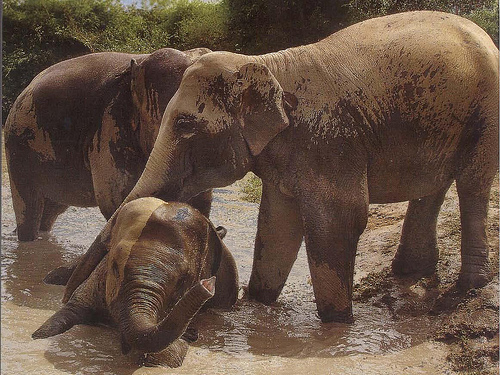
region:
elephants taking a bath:
[5, 8, 498, 365]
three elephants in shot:
[4, 8, 499, 365]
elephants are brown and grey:
[1, 10, 499, 365]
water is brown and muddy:
[1, 127, 453, 374]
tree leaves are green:
[1, 0, 498, 112]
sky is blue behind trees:
[104, 1, 161, 13]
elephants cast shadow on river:
[1, 227, 491, 373]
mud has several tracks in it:
[359, 207, 499, 374]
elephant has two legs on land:
[121, 7, 499, 323]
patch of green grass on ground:
[238, 176, 263, 203]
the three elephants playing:
[5, 12, 499, 367]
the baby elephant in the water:
[47, 204, 266, 364]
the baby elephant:
[38, 193, 250, 373]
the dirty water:
[224, 300, 352, 370]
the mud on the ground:
[396, 287, 491, 371]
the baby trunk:
[110, 280, 227, 352]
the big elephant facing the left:
[90, 6, 493, 344]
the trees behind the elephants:
[4, 0, 496, 97]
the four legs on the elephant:
[250, 175, 499, 321]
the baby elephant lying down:
[32, 190, 261, 368]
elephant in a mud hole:
[8, 186, 250, 371]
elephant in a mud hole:
[0, 35, 235, 254]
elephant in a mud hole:
[39, 8, 499, 339]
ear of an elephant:
[225, 50, 303, 166]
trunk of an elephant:
[97, 253, 221, 357]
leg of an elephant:
[290, 173, 387, 328]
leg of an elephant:
[229, 181, 313, 317]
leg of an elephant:
[380, 172, 460, 287]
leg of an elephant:
[447, 156, 498, 288]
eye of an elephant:
[173, 115, 200, 141]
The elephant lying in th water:
[30, 193, 242, 367]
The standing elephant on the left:
[1, 42, 231, 254]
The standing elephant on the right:
[58, 6, 499, 328]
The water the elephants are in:
[1, 124, 451, 374]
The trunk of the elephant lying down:
[122, 266, 221, 356]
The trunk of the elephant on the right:
[56, 153, 196, 308]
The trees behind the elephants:
[2, 1, 497, 122]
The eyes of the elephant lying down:
[107, 255, 188, 295]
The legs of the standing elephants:
[4, 163, 499, 325]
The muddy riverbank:
[345, 196, 499, 374]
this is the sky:
[123, 1, 141, 8]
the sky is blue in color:
[123, 0, 138, 8]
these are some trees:
[13, 5, 296, 40]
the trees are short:
[15, 5, 273, 44]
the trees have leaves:
[84, 5, 186, 44]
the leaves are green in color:
[28, 5, 165, 48]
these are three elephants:
[6, 16, 476, 281]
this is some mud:
[455, 300, 480, 333]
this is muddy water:
[237, 320, 280, 355]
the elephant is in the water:
[51, 202, 238, 345]